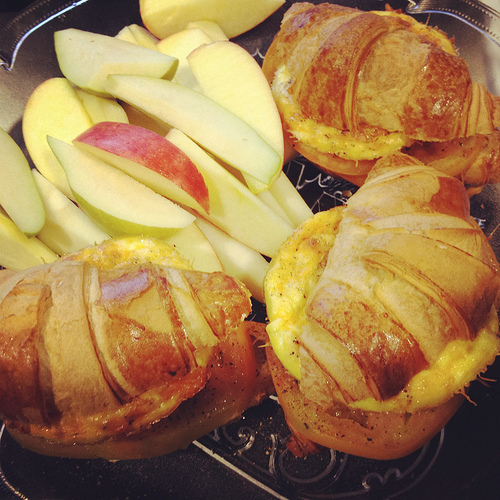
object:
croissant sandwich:
[260, 0, 500, 202]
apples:
[0, 0, 315, 307]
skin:
[0, 0, 314, 307]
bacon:
[0, 236, 275, 460]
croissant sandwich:
[0, 241, 280, 460]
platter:
[0, 0, 499, 500]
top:
[261, 0, 500, 161]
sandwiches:
[258, 0, 499, 462]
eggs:
[263, 152, 500, 463]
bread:
[263, 151, 500, 462]